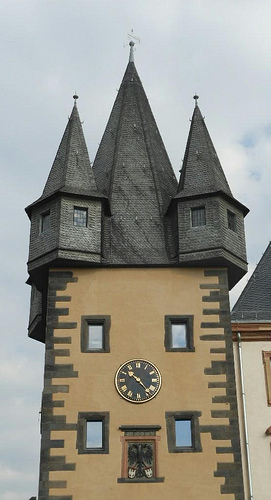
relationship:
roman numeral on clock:
[136, 393, 141, 399] [115, 358, 162, 403]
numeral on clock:
[117, 375, 125, 385] [92, 342, 188, 418]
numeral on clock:
[126, 363, 133, 372] [115, 358, 162, 403]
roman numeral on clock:
[142, 362, 148, 369] [115, 358, 162, 403]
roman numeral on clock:
[144, 386, 157, 394] [113, 354, 164, 403]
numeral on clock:
[125, 389, 133, 398] [104, 354, 173, 403]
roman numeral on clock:
[133, 359, 140, 369] [113, 354, 164, 403]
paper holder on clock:
[115, 359, 162, 404] [113, 354, 164, 403]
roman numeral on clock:
[147, 367, 157, 376] [113, 354, 164, 403]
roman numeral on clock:
[147, 381, 157, 391] [113, 354, 164, 403]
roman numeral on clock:
[133, 389, 142, 400] [113, 354, 164, 403]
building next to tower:
[231, 239, 270, 498] [25, 29, 250, 500]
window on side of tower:
[75, 409, 110, 455] [25, 29, 250, 500]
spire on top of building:
[92, 28, 180, 259] [36, 266, 246, 498]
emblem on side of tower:
[115, 432, 168, 484] [25, 29, 250, 500]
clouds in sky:
[235, 125, 267, 186] [1, 1, 269, 497]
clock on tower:
[113, 354, 164, 403] [23, 28, 269, 498]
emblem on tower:
[118, 425, 161, 479] [83, 30, 179, 268]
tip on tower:
[123, 29, 140, 63] [90, 29, 185, 265]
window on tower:
[81, 315, 110, 352] [30, 40, 235, 461]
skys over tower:
[0, 1, 269, 498] [26, 35, 250, 287]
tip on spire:
[122, 28, 140, 60] [90, 28, 175, 263]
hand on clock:
[126, 370, 136, 378] [115, 358, 162, 403]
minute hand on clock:
[139, 382, 150, 395] [108, 356, 168, 402]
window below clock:
[169, 413, 197, 447] [111, 359, 160, 400]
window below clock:
[77, 411, 109, 453] [111, 359, 160, 400]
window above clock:
[80, 315, 109, 352] [115, 358, 162, 403]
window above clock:
[164, 314, 194, 351] [115, 358, 162, 403]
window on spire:
[38, 208, 51, 232] [23, 89, 108, 272]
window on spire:
[72, 206, 87, 227] [23, 89, 108, 272]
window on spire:
[189, 206, 206, 226] [166, 92, 248, 272]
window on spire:
[226, 209, 236, 233] [166, 92, 248, 272]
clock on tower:
[115, 358, 162, 403] [25, 29, 250, 500]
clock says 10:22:
[115, 358, 162, 403] [120, 364, 153, 398]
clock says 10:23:
[115, 358, 162, 403] [115, 363, 153, 401]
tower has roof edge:
[18, 19, 252, 419] [69, 179, 99, 192]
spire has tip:
[172, 102, 232, 186] [194, 94, 201, 105]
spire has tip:
[102, 61, 180, 257] [124, 27, 145, 61]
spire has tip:
[40, 109, 100, 186] [67, 90, 81, 105]